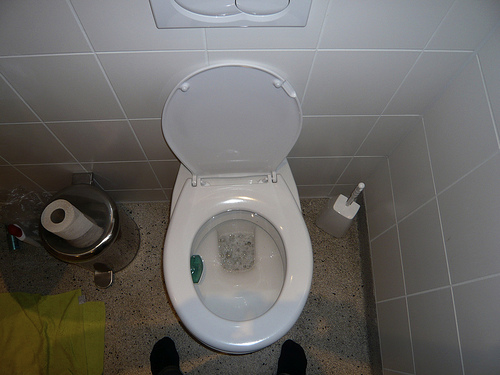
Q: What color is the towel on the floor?
A: Yellow.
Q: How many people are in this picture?
A: One.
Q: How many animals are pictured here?
A: Zero.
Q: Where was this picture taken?
A: A bathroom.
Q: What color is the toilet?
A: White.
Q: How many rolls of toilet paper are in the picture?
A: One.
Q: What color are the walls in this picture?
A: White.